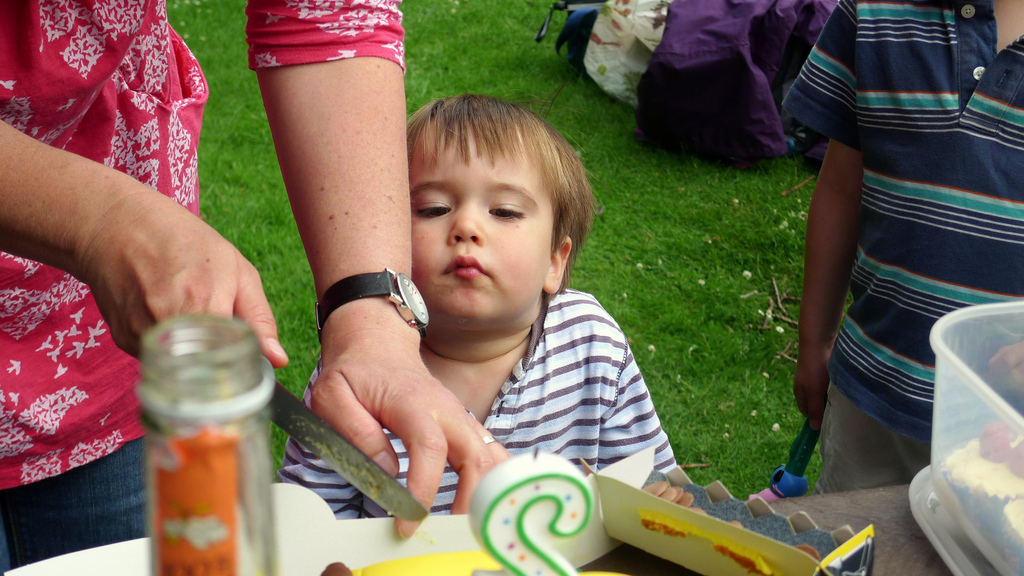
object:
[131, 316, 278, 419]
top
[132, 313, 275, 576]
bottle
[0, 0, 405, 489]
shirt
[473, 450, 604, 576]
candle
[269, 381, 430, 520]
butter knife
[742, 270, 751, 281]
flower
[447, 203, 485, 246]
nose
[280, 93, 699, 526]
boy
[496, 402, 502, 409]
button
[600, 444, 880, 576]
cardboard box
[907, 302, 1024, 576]
plastic container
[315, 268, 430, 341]
watch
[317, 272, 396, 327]
band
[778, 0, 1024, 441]
shirt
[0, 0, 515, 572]
person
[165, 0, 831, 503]
grass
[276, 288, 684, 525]
shirt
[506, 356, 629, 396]
stripe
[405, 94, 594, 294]
hair